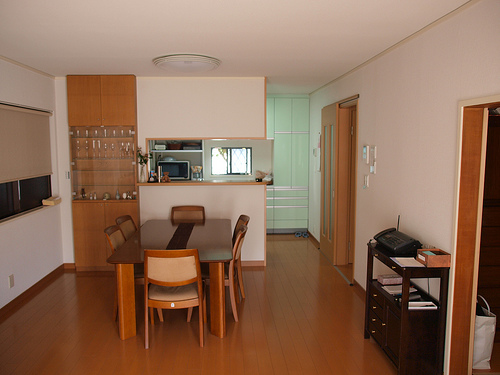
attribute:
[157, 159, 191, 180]
microwave — small, black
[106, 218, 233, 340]
table — large, brown, wooden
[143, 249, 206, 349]
chair — wooden, brown, tan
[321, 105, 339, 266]
door — wood, glass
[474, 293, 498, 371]
bag — paper, white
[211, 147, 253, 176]
window — glass, small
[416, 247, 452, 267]
box — wooden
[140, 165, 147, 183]
vase — ceramic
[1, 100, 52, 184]
shade — beige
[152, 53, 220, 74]
light — round, circular, flat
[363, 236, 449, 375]
table — small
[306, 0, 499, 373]
wall — white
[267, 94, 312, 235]
wall — green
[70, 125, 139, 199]
shelves — small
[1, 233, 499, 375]
floor — brown, shiny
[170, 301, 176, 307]
spot — white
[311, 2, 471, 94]
edge — brown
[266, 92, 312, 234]
tile — green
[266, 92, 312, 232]
cabinets — green, white, floor to ceiling